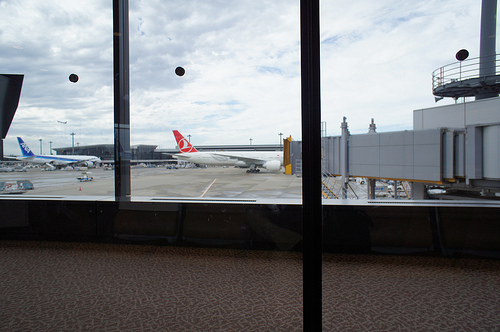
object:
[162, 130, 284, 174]
plane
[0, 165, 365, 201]
runway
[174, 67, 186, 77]
circle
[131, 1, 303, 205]
window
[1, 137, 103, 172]
airrport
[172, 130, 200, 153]
tail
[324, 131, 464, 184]
fence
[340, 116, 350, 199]
pole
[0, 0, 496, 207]
glass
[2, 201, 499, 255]
reflection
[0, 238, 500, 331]
carpet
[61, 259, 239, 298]
pattern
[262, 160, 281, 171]
engine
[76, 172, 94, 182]
car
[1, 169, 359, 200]
cement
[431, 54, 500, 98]
balcony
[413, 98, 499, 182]
building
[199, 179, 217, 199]
line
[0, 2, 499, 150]
sky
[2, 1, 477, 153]
clouds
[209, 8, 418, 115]
patches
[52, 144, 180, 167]
building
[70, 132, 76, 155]
street lamps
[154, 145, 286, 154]
bridge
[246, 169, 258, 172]
wheels